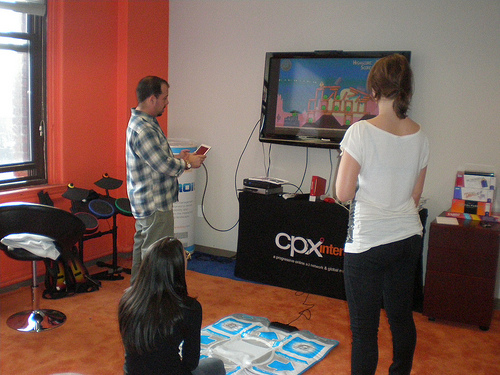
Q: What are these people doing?
A: Playing a video game.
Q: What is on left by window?
A: A chair.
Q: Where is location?
A: Inside house.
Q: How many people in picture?
A: Three.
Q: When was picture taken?
A: During daylight.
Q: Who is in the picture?
A: Three people.